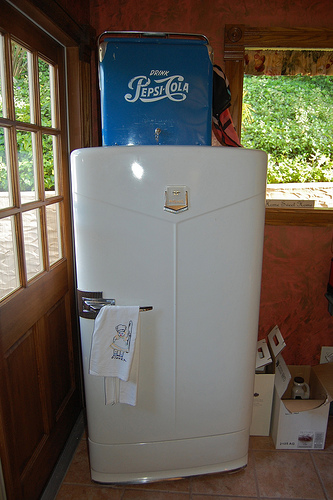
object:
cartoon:
[110, 320, 134, 362]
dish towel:
[88, 305, 140, 407]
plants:
[240, 74, 332, 183]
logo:
[125, 69, 189, 103]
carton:
[270, 355, 333, 449]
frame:
[0, 1, 82, 500]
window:
[0, 34, 65, 302]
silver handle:
[99, 31, 209, 44]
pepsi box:
[97, 30, 212, 145]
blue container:
[98, 31, 212, 148]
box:
[270, 354, 333, 450]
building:
[0, 0, 333, 500]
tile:
[53, 435, 333, 500]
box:
[249, 326, 286, 436]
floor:
[53, 427, 333, 500]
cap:
[295, 377, 305, 383]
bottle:
[292, 376, 310, 399]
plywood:
[0, 263, 83, 499]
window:
[240, 74, 332, 212]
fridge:
[70, 145, 267, 485]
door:
[0, 0, 83, 500]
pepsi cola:
[125, 70, 189, 102]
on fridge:
[70, 146, 267, 483]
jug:
[292, 377, 310, 400]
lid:
[294, 376, 304, 383]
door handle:
[83, 297, 153, 319]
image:
[110, 320, 132, 361]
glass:
[0, 39, 62, 300]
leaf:
[300, 114, 304, 121]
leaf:
[280, 133, 288, 139]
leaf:
[257, 120, 265, 125]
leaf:
[273, 92, 285, 101]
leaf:
[272, 84, 281, 91]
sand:
[266, 181, 332, 205]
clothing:
[212, 64, 242, 147]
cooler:
[97, 30, 213, 147]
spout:
[155, 127, 161, 135]